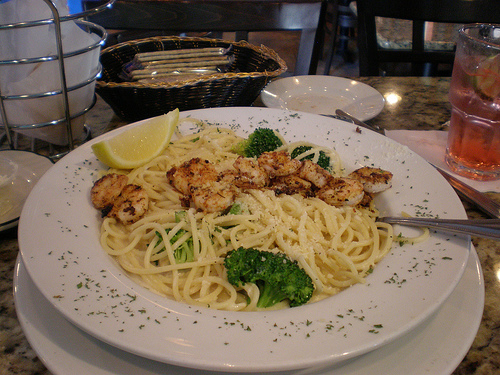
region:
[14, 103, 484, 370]
a white bowl on a white plate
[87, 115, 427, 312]
pasta in a white bowl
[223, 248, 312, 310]
a small head of broccoli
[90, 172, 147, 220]
two bits of chicken on top of a pasta bowl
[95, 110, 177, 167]
a slice of lemon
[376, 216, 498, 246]
top of a utensil buried inside a bowl of pasta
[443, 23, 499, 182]
a glass of rose wine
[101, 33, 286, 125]
a wicker basket on a table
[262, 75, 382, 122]
a small white plate on a table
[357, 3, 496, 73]
black seat of a chair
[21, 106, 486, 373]
shallow bowl sitting on a plate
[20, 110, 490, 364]
pasta dish in the bowl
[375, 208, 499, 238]
silver handle sticking out of the bowl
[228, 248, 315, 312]
hunk of green broccoli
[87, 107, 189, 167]
half of a lemon on the edge of the bowl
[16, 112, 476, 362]
green specks around the edge of the plate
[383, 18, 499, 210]
glass sitting on a napkin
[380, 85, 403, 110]
light glare on the table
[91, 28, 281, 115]
basket on the table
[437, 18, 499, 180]
small glass with liquid in it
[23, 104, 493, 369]
food in a shallow white bowl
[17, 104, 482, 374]
white bowl on a white plate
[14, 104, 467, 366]
green specks around the edge of the bowl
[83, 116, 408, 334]
pasta in a bowl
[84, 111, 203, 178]
half of a lemon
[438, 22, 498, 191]
small glass of liquid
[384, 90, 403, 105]
light glare on the table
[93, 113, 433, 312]
Noodles on the plate.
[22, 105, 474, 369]
Green spice on the plate.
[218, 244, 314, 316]
Broccoli on the plate.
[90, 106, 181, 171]
Lemon slice on the plate.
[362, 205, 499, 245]
Metal eating utensil on the plate.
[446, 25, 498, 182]
Drink on the table.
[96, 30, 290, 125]
Basket on the table.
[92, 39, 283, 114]
Crackers in the basket.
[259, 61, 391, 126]
small white plate on the table.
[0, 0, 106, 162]
metal basket on the table.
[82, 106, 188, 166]
Slice of lemon on dish.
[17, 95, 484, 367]
Large white dish filled with food.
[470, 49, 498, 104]
Piece of lime in drink.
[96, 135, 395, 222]
A line of grilled shrimp.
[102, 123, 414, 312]
Pasta topped with broccoli and shrimp.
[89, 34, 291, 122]
Dark brown basket with light brown rim.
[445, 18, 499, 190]
Glass of pink colored liquid.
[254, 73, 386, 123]
Empty white saucer near basket.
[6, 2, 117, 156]
Holder made of metal rings.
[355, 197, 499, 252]
Silver utensil in pasta.